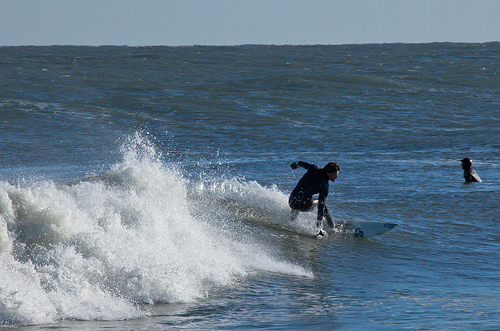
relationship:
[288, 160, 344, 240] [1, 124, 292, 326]
man riding waves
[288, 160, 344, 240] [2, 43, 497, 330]
man in water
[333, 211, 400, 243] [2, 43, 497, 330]
surfboard in water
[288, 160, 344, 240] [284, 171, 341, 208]
man wearing wetsuit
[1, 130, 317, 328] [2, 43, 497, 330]
waves in water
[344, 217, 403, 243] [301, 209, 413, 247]
decals on surfboard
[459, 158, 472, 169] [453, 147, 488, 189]
hat on person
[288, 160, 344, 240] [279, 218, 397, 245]
man standing on a surfboard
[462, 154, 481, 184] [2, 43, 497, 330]
man sitting in water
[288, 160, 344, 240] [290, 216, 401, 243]
man riding on surfboard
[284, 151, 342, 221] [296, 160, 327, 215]
man wearing wetsuit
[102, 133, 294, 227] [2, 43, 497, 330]
splash from water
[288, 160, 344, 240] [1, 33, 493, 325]
man at beach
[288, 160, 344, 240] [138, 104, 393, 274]
man in water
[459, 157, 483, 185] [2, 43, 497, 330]
man in water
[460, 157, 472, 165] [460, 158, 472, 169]
hat on mans head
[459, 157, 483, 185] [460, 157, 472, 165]
man wearing a hat